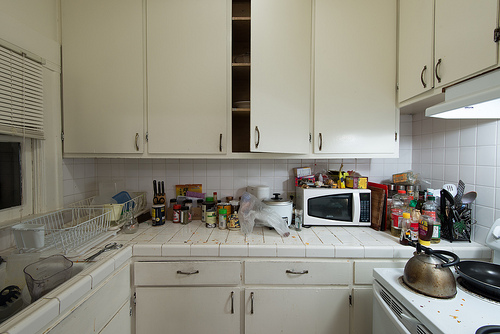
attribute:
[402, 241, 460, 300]
teapot — stainless steel, silver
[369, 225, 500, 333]
stove — white, white enamel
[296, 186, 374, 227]
microwave — white, black, small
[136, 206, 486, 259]
counter — tiled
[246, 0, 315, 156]
door — open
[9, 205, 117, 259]
dish drainer — empty, white, plastic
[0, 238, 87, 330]
sink — dirty, full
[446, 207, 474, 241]
caddy — black, full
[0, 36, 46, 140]
blinds — mini, slatted, white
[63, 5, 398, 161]
cupboards — white, wooden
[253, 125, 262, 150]
handles — silver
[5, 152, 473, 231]
kitchen — messy, white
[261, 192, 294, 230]
rice cooker — white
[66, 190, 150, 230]
dish rack — plastic, white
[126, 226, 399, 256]
tile — white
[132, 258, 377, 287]
drawer — wooden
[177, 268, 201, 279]
handle — metal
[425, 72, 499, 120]
light — on